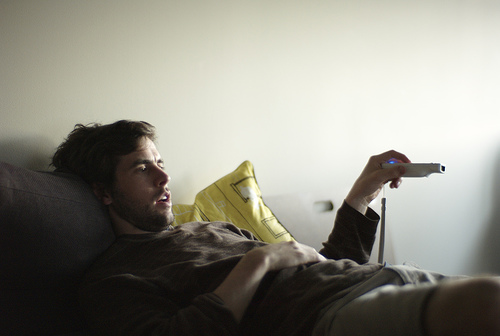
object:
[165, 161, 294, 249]
pillow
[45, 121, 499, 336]
man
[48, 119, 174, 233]
head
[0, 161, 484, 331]
bed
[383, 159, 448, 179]
remote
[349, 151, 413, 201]
man's hand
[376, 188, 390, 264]
cord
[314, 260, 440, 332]
underwear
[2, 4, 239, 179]
wall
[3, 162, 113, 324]
black pillow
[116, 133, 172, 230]
man's face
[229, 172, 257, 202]
pattern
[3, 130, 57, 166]
shadow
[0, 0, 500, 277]
wall